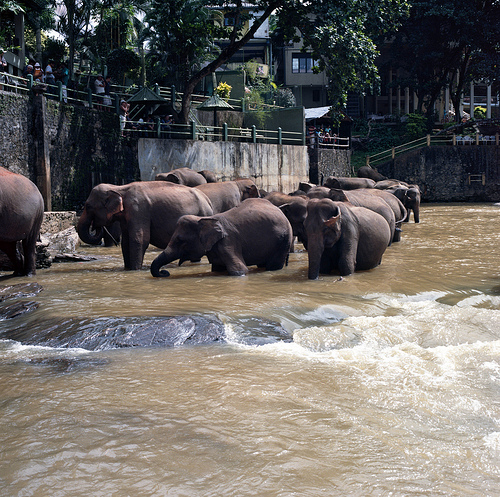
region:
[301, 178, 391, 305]
Large elephant in water.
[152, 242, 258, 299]
Gray elephant bending down in water.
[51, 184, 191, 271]
Large elephant in water.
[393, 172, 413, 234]
Elephant in water drinking.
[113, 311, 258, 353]
Water pouring over rocks.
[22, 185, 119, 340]
Elephant standing near wall.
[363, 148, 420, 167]
Yellow railing on concrete.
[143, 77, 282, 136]
Umbrellas near the table and chairs.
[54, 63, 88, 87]
Person wearing blue shirt.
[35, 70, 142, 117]
Group of people up above looking down at the elephants.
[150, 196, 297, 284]
an elephant in the water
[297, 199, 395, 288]
an elephant in the water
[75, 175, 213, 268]
an elephant in the water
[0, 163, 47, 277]
an elephant in the water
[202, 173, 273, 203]
an elephant in the water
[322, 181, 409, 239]
an elephant in the water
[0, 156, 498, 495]
elephants in a stream of water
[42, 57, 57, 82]
a person watching elephants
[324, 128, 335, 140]
a person watching elephants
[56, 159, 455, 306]
A group of elephants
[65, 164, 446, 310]
A group of grey elephants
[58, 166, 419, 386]
A group of elephants in the water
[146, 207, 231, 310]
The head of an elephant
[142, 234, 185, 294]
The trunk of an elephant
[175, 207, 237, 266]
The ear of an elephant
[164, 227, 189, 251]
The eye of an elephant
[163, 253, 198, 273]
The open mouth of an elephant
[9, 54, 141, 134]
people looking at a group of elephants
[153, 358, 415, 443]
water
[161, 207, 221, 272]
the head of an elephant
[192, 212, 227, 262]
the ear of an elephant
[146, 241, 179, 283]
the trunk of an elephant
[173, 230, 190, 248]
the eye of an elephant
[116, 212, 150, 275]
the leg of an elephant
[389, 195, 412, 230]
the tail of an elephant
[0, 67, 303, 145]
a small wooden fence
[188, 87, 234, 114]
a green overhang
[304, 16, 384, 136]
a green tree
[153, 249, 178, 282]
part of elephant trunk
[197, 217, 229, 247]
an ear on elephant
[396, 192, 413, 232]
tail on the elephant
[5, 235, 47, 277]
hind legs of elephant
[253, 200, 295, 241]
rear end of elephant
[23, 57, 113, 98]
people looking at elephants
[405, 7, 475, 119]
trees behind elephants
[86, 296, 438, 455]
water near the elephants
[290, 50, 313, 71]
windows in building behind elephants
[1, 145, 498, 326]
elephants in the water drinking